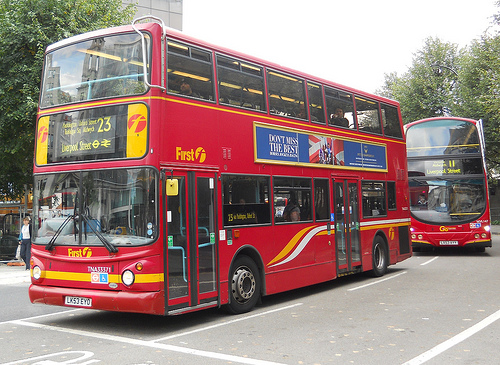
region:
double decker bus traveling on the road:
[25, 25, 412, 306]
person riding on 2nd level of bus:
[328, 102, 348, 127]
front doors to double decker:
[162, 167, 218, 313]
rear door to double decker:
[330, 172, 360, 272]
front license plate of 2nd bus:
[437, 238, 457, 244]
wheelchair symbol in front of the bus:
[99, 272, 109, 284]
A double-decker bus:
[72, 24, 405, 299]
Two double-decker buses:
[32, 19, 494, 305]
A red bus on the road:
[35, 17, 398, 314]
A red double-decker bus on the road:
[28, 9, 426, 294]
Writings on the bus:
[160, 119, 328, 171]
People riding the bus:
[236, 84, 356, 126]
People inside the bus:
[220, 77, 362, 137]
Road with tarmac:
[296, 265, 468, 354]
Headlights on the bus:
[10, 247, 155, 296]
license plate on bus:
[65, 296, 101, 311]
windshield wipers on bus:
[46, 215, 117, 252]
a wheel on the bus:
[229, 256, 261, 301]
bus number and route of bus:
[59, 115, 126, 152]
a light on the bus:
[124, 271, 134, 283]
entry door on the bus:
[167, 176, 216, 306]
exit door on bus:
[332, 182, 362, 272]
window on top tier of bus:
[49, 48, 139, 97]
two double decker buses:
[32, 28, 497, 328]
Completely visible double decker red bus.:
[29, 23, 413, 318]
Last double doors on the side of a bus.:
[328, 174, 363, 278]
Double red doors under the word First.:
[157, 162, 221, 312]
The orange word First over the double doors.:
[175, 146, 196, 161]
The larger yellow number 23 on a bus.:
[95, 116, 110, 132]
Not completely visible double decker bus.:
[400, 115, 490, 250]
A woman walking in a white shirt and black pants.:
[16, 216, 31, 271]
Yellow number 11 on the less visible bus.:
[447, 157, 453, 167]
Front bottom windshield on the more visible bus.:
[31, 167, 159, 249]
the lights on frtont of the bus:
[30, 220, 494, 286]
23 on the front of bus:
[95, 114, 116, 139]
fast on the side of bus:
[174, 143, 196, 163]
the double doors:
[163, 165, 366, 311]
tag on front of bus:
[63, 235, 460, 313]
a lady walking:
[15, 213, 35, 269]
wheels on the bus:
[225, 230, 386, 307]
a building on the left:
[95, 0, 187, 34]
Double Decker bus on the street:
[27, 23, 416, 318]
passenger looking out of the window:
[328, 104, 352, 121]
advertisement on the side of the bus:
[246, 114, 394, 177]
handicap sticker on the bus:
[99, 273, 109, 283]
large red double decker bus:
[25, 10, 415, 320]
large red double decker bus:
[395, 110, 495, 256]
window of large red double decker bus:
[162, 37, 217, 102]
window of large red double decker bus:
[213, 47, 265, 113]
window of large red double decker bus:
[265, 65, 307, 120]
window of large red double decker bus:
[305, 75, 326, 125]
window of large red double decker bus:
[322, 81, 357, 129]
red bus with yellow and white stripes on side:
[27, 13, 423, 318]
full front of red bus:
[402, 115, 493, 256]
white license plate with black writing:
[62, 294, 95, 307]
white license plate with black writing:
[440, 238, 457, 247]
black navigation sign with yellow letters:
[423, 159, 463, 174]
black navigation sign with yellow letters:
[58, 115, 115, 154]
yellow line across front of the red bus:
[28, 265, 164, 284]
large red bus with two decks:
[28, 12, 413, 317]